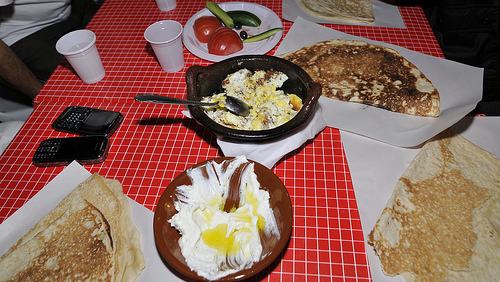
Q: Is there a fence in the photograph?
A: No, there are no fences.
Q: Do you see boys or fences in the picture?
A: No, there are no fences or boys.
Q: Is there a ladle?
A: No, there are no ladles.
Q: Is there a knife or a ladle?
A: No, there are no ladles or knives.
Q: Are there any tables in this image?
A: Yes, there is a table.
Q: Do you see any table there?
A: Yes, there is a table.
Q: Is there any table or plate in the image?
A: Yes, there is a table.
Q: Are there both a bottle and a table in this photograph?
A: No, there is a table but no bottles.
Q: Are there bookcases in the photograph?
A: No, there are no bookcases.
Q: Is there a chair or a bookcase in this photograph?
A: No, there are no bookcases or chairs.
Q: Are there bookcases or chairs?
A: No, there are no bookcases or chairs.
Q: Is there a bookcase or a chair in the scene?
A: No, there are no bookcases or chairs.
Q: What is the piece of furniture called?
A: The piece of furniture is a table.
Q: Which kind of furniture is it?
A: The piece of furniture is a table.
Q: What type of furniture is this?
A: This is a table.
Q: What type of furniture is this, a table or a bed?
A: This is a table.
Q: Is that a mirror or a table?
A: That is a table.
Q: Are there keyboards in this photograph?
A: No, there are no keyboards.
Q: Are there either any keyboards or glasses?
A: No, there are no keyboards or glasses.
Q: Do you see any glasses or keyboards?
A: No, there are no keyboards or glasses.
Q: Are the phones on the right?
A: No, the phones are on the left of the image.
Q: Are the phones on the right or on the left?
A: The phones are on the left of the image.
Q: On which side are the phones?
A: The phones are on the left of the image.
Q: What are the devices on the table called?
A: The devices are phones.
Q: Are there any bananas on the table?
A: No, there are phones on the table.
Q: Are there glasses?
A: No, there are no glasses.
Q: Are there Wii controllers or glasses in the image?
A: No, there are no glasses or Wii controllers.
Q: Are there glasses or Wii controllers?
A: No, there are no glasses or Wii controllers.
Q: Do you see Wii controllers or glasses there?
A: No, there are no glasses or Wii controllers.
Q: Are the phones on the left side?
A: Yes, the phones are on the left of the image.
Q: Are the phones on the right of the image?
A: No, the phones are on the left of the image.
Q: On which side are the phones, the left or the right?
A: The phones are on the left of the image.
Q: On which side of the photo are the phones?
A: The phones are on the left of the image.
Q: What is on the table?
A: The phones are on the table.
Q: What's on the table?
A: The phones are on the table.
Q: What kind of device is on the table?
A: The devices are phones.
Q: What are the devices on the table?
A: The devices are phones.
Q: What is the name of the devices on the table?
A: The devices are phones.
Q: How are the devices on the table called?
A: The devices are phones.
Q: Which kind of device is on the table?
A: The devices are phones.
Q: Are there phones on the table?
A: Yes, there are phones on the table.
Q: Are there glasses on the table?
A: No, there are phones on the table.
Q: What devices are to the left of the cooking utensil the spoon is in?
A: The devices are phones.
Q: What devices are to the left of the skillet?
A: The devices are phones.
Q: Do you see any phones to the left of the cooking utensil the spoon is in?
A: Yes, there are phones to the left of the skillet.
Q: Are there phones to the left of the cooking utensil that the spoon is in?
A: Yes, there are phones to the left of the skillet.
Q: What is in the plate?
A: The egg is in the plate.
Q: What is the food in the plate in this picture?
A: The food is an egg.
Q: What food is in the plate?
A: The food is an egg.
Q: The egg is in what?
A: The egg is in the plate.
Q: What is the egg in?
A: The egg is in the plate.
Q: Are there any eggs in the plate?
A: Yes, there is an egg in the plate.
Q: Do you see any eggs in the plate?
A: Yes, there is an egg in the plate.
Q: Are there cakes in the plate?
A: No, there is an egg in the plate.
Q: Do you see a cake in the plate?
A: No, there is an egg in the plate.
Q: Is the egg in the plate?
A: Yes, the egg is in the plate.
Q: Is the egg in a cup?
A: No, the egg is in the plate.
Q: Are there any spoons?
A: Yes, there is a spoon.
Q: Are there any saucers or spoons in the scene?
A: Yes, there is a spoon.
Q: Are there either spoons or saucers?
A: Yes, there is a spoon.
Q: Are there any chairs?
A: No, there are no chairs.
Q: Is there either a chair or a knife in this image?
A: No, there are no chairs or knives.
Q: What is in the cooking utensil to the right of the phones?
A: The spoon is in the skillet.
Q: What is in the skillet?
A: The spoon is in the skillet.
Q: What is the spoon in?
A: The spoon is in the skillet.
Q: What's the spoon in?
A: The spoon is in the skillet.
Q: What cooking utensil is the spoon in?
A: The spoon is in the skillet.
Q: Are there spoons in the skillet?
A: Yes, there is a spoon in the skillet.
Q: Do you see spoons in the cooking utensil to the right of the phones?
A: Yes, there is a spoon in the skillet.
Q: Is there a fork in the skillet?
A: No, there is a spoon in the skillet.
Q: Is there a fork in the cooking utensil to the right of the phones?
A: No, there is a spoon in the skillet.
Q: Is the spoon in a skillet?
A: Yes, the spoon is in a skillet.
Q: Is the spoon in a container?
A: No, the spoon is in a skillet.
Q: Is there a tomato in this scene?
A: Yes, there is a tomato.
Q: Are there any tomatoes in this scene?
A: Yes, there is a tomato.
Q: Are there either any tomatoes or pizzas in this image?
A: Yes, there is a tomato.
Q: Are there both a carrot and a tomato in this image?
A: No, there is a tomato but no carrots.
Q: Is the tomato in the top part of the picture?
A: Yes, the tomato is in the top of the image.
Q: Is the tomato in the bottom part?
A: No, the tomato is in the top of the image.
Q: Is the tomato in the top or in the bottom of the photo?
A: The tomato is in the top of the image.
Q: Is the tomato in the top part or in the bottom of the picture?
A: The tomato is in the top of the image.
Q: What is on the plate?
A: The tomato is on the plate.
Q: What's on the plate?
A: The tomato is on the plate.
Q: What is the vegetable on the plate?
A: The vegetable is a tomato.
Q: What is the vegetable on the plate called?
A: The vegetable is a tomato.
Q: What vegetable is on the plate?
A: The vegetable is a tomato.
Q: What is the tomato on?
A: The tomato is on the plate.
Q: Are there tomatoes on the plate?
A: Yes, there is a tomato on the plate.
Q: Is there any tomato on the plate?
A: Yes, there is a tomato on the plate.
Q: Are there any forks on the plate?
A: No, there is a tomato on the plate.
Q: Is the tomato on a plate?
A: Yes, the tomato is on a plate.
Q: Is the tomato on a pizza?
A: No, the tomato is on a plate.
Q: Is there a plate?
A: Yes, there is a plate.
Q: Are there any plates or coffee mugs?
A: Yes, there is a plate.